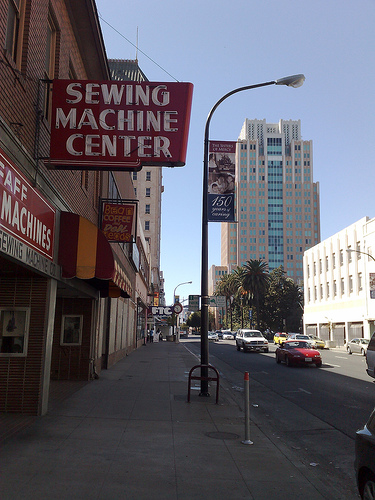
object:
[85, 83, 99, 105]
letter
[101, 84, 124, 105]
letter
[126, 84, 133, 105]
letter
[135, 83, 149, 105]
letter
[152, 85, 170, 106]
letter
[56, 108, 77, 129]
letter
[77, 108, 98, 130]
letter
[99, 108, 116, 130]
letter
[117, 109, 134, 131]
letter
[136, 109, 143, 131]
letter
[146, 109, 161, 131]
letter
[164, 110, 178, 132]
letter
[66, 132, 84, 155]
letter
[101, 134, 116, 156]
letter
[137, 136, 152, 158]
letter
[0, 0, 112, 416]
building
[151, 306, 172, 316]
sign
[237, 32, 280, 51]
clouds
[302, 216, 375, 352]
building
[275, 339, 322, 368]
car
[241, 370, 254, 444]
pole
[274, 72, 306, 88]
light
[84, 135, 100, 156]
letter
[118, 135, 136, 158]
letter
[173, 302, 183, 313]
clock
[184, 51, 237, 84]
clouds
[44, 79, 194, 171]
sign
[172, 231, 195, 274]
clouds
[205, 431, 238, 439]
manhole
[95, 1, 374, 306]
blue sky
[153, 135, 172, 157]
letter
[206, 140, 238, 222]
banner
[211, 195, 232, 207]
150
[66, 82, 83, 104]
letter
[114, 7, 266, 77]
clouds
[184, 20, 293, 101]
clouds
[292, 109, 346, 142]
clouds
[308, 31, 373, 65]
clouds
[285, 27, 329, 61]
clouds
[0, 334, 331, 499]
sidewalk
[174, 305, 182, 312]
face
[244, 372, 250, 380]
top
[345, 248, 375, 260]
lamp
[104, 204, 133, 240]
coffee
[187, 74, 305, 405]
post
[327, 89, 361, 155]
clouds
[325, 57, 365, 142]
clouds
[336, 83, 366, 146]
clouds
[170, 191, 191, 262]
clouds